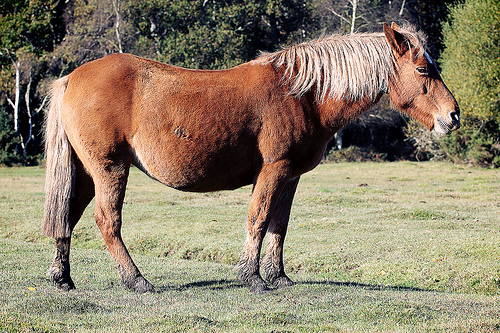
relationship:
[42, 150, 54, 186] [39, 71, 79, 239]
edge of tail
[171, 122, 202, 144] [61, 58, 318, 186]
scar on body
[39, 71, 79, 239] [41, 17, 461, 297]
tail on horse